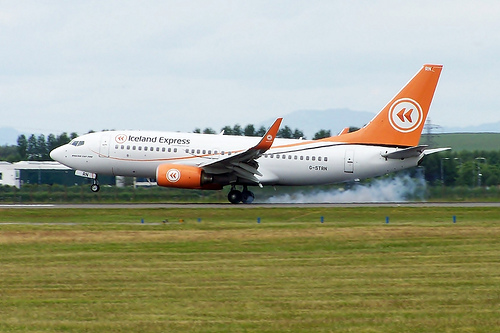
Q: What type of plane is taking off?
A: Passenger.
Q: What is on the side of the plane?
A: Windows.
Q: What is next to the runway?
A: Green grass.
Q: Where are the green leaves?
A: Trees.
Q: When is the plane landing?
A: The plane is landing in the daytime.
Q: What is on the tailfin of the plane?
A: There is a circle with two arrows on the tailfin.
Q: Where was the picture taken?
A: An airport.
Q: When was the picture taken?
A: Daytime.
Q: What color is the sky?
A: Gray.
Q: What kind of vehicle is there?
A: An airplane.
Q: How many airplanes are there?
A: One.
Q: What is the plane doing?
A: Landing.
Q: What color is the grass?
A: Green.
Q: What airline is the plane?
A: Iceland Express.